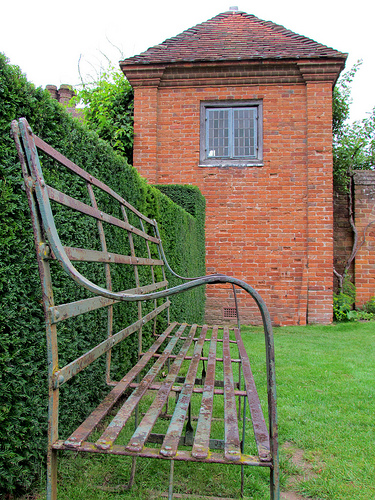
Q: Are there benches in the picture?
A: Yes, there is a bench.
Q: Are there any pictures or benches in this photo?
A: Yes, there is a bench.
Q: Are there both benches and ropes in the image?
A: No, there is a bench but no ropes.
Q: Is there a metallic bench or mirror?
A: Yes, there is a metal bench.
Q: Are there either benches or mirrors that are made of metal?
A: Yes, the bench is made of metal.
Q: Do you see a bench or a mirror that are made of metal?
A: Yes, the bench is made of metal.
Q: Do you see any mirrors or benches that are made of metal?
A: Yes, the bench is made of metal.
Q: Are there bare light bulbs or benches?
A: Yes, there is a bare bench.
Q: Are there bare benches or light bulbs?
A: Yes, there is a bare bench.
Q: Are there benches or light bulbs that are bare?
A: Yes, the bench is bare.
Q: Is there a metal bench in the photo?
A: Yes, there is a bench that is made of metal.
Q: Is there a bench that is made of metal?
A: Yes, there is a bench that is made of metal.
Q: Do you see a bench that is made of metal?
A: Yes, there is a bench that is made of metal.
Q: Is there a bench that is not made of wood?
A: Yes, there is a bench that is made of metal.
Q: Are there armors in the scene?
A: No, there are no armors.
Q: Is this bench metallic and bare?
A: Yes, the bench is metallic and bare.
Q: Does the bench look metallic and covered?
A: No, the bench is metallic but bare.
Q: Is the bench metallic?
A: Yes, the bench is metallic.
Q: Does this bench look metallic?
A: Yes, the bench is metallic.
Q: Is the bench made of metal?
A: Yes, the bench is made of metal.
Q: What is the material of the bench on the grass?
A: The bench is made of metal.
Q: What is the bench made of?
A: The bench is made of metal.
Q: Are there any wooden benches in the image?
A: No, there is a bench but it is metallic.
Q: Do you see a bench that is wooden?
A: No, there is a bench but it is metallic.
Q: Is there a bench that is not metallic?
A: No, there is a bench but it is metallic.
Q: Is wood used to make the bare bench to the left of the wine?
A: No, the bench is made of metal.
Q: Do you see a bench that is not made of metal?
A: No, there is a bench but it is made of metal.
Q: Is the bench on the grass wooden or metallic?
A: The bench is metallic.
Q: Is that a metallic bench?
A: Yes, that is a metallic bench.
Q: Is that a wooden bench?
A: No, that is a metallic bench.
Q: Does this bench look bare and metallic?
A: Yes, the bench is bare and metallic.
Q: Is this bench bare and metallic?
A: Yes, the bench is bare and metallic.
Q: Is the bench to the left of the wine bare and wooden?
A: No, the bench is bare but metallic.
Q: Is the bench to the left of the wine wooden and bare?
A: No, the bench is bare but metallic.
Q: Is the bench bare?
A: Yes, the bench is bare.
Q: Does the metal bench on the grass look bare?
A: Yes, the bench is bare.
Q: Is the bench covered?
A: No, the bench is bare.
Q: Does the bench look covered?
A: No, the bench is bare.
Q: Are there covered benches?
A: No, there is a bench but it is bare.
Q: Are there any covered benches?
A: No, there is a bench but it is bare.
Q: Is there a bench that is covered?
A: No, there is a bench but it is bare.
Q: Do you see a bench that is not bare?
A: No, there is a bench but it is bare.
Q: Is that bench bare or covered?
A: The bench is bare.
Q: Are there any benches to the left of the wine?
A: Yes, there is a bench to the left of the wine.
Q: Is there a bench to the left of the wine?
A: Yes, there is a bench to the left of the wine.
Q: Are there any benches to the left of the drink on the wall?
A: Yes, there is a bench to the left of the wine.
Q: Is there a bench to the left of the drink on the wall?
A: Yes, there is a bench to the left of the wine.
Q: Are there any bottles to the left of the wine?
A: No, there is a bench to the left of the wine.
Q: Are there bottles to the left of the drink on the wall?
A: No, there is a bench to the left of the wine.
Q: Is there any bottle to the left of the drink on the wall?
A: No, there is a bench to the left of the wine.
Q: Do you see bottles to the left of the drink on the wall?
A: No, there is a bench to the left of the wine.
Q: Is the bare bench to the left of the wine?
A: Yes, the bench is to the left of the wine.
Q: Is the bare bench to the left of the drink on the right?
A: Yes, the bench is to the left of the wine.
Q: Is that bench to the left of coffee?
A: No, the bench is to the left of the wine.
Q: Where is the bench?
A: The bench is on the grass.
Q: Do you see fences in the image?
A: No, there are no fences.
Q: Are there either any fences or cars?
A: No, there are no fences or cars.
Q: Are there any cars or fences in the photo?
A: No, there are no fences or cars.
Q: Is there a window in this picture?
A: Yes, there is a window.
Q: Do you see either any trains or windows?
A: Yes, there is a window.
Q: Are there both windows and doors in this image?
A: No, there is a window but no doors.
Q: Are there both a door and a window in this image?
A: No, there is a window but no doors.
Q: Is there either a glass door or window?
A: Yes, there is a glass window.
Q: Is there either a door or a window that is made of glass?
A: Yes, the window is made of glass.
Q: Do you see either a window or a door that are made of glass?
A: Yes, the window is made of glass.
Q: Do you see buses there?
A: No, there are no buses.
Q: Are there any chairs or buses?
A: No, there are no buses or chairs.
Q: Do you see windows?
A: Yes, there is a window.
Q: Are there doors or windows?
A: Yes, there is a window.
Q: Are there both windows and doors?
A: No, there is a window but no doors.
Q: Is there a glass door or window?
A: Yes, there is a glass window.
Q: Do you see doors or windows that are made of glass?
A: Yes, the window is made of glass.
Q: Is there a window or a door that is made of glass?
A: Yes, the window is made of glass.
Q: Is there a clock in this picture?
A: No, there are no clocks.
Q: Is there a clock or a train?
A: No, there are no clocks or trains.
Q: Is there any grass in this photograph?
A: Yes, there is grass.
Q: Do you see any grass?
A: Yes, there is grass.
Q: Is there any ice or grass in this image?
A: Yes, there is grass.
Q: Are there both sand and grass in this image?
A: No, there is grass but no sand.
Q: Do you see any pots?
A: No, there are no pots.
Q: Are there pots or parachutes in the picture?
A: No, there are no pots or parachutes.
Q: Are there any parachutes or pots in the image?
A: No, there are no pots or parachutes.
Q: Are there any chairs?
A: No, there are no chairs.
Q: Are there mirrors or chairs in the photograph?
A: No, there are no chairs or mirrors.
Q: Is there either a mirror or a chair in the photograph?
A: No, there are no chairs or mirrors.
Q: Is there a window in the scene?
A: Yes, there is a window.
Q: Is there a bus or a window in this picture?
A: Yes, there is a window.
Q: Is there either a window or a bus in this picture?
A: Yes, there is a window.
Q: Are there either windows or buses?
A: Yes, there is a window.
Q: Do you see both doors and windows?
A: No, there is a window but no doors.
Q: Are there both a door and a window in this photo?
A: No, there is a window but no doors.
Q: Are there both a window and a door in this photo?
A: No, there is a window but no doors.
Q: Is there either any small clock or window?
A: Yes, there is a small window.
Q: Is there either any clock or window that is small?
A: Yes, the window is small.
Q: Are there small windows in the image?
A: Yes, there is a small window.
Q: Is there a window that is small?
A: Yes, there is a window that is small.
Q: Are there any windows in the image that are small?
A: Yes, there is a window that is small.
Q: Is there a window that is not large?
A: Yes, there is a small window.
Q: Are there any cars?
A: No, there are no cars.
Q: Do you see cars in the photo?
A: No, there are no cars.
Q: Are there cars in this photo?
A: No, there are no cars.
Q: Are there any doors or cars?
A: No, there are no cars or doors.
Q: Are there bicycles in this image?
A: No, there are no bicycles.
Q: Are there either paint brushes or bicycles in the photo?
A: No, there are no bicycles or paint brushes.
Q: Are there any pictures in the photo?
A: No, there are no pictures.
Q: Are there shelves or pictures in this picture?
A: No, there are no pictures or shelves.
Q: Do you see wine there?
A: Yes, there is wine.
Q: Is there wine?
A: Yes, there is wine.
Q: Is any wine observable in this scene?
A: Yes, there is wine.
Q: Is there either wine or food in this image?
A: Yes, there is wine.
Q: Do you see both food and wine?
A: No, there is wine but no food.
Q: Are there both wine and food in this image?
A: No, there is wine but no food.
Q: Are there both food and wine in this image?
A: No, there is wine but no food.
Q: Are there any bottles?
A: No, there are no bottles.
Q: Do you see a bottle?
A: No, there are no bottles.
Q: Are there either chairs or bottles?
A: No, there are no bottles or chairs.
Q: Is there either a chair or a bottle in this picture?
A: No, there are no bottles or chairs.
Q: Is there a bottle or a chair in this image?
A: No, there are no bottles or chairs.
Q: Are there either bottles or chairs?
A: No, there are no bottles or chairs.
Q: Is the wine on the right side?
A: Yes, the wine is on the right of the image.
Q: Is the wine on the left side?
A: No, the wine is on the right of the image.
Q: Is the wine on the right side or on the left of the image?
A: The wine is on the right of the image.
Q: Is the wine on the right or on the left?
A: The wine is on the right of the image.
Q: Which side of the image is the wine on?
A: The wine is on the right of the image.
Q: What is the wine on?
A: The wine is on the wall.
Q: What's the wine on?
A: The wine is on the wall.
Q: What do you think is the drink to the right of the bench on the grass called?
A: The drink is wine.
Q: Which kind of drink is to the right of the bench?
A: The drink is wine.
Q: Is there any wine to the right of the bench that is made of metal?
A: Yes, there is wine to the right of the bench.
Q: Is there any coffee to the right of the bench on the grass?
A: No, there is wine to the right of the bench.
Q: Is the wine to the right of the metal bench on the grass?
A: Yes, the wine is to the right of the bench.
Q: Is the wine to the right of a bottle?
A: No, the wine is to the right of the bench.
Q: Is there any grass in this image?
A: Yes, there is grass.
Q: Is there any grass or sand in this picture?
A: Yes, there is grass.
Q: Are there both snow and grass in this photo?
A: No, there is grass but no snow.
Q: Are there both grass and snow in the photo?
A: No, there is grass but no snow.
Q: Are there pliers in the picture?
A: No, there are no pliers.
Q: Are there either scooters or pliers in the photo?
A: No, there are no pliers or scooters.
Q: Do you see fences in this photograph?
A: No, there are no fences.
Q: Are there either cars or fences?
A: No, there are no fences or cars.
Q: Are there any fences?
A: No, there are no fences.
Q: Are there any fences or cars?
A: No, there are no fences or cars.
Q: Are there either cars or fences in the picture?
A: No, there are no fences or cars.